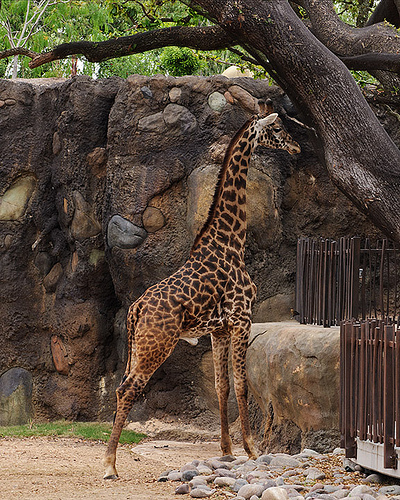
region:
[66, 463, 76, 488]
the soil is brown and dry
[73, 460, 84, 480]
the soil is brown and dry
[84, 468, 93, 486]
the soil is brown and dry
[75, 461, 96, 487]
the soil is brown and dry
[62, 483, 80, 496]
the soil is brown and dry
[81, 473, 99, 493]
the soil is brown and dry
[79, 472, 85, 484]
the soil is brown and dry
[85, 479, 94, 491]
the soil is brown and dry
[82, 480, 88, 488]
the soil is brown and dry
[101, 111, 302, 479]
A giraffe standing up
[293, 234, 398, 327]
A metal fence in front of a giraffe.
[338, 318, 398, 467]
Metal rails on a fence to the giraffes right.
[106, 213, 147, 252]
Gray stone sticking out of a large rock wall.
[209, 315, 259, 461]
Two front legs of a giraffe.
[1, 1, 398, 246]
A thick tree trunk and branches.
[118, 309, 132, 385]
A long thing giraffe tail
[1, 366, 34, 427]
A large rock on a rock wall at the bottom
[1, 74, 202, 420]
A large rock wall beside a giraffe.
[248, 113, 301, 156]
Head of a giraffe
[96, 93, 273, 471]
a giraffe in the zoo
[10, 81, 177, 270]
a stone wall structure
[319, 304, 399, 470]
a metal fence to keep people out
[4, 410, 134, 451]
green grass on the ground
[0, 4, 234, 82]
green leaves in the trees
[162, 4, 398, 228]
tall trees for the giraffe to eat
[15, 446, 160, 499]
brown dirt ground near the giraffe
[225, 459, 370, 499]
round stones on the ground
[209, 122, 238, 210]
brown hair on the giraffe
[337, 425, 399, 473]
a white standing area for people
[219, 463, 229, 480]
the rocks are big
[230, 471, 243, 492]
the rocks are big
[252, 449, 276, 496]
the rocks are big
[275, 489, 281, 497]
the rocks are big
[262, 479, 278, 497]
the rocks are big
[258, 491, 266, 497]
the rocks are big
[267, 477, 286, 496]
the rocks are big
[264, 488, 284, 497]
the rocks are big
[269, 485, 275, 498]
the rocks are big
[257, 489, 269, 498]
the rocks are big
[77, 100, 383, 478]
giraffe in man-made pen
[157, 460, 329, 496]
round rocks on the pen's grounds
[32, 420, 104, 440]
patch of green grass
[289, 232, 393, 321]
section of stick fencing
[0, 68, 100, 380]
confinement wall at the zoo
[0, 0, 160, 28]
wooded area outside the pen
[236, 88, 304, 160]
head of the giraffe, with ears and ossicones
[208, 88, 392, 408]
animal looks over the fencing of its pen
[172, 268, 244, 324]
distinctive coat pattern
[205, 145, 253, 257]
elongate neck of an adult giraffe